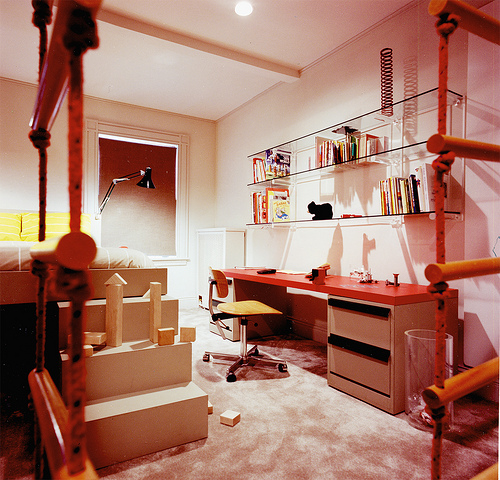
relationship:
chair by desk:
[217, 285, 261, 366] [293, 282, 294, 283]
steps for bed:
[128, 393, 187, 449] [6, 263, 32, 275]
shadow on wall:
[470, 422, 489, 439] [480, 287, 493, 311]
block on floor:
[110, 416, 155, 456] [342, 439, 356, 453]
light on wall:
[241, 0, 255, 23] [480, 287, 493, 311]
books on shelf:
[383, 172, 409, 206] [320, 201, 376, 223]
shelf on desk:
[320, 201, 376, 223] [293, 282, 294, 283]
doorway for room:
[114, 114, 191, 149] [57, 9, 485, 360]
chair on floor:
[217, 285, 261, 366] [342, 439, 356, 453]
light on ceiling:
[241, 0, 255, 23] [333, 6, 353, 13]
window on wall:
[177, 139, 193, 158] [480, 287, 493, 311]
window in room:
[177, 139, 193, 158] [57, 9, 485, 360]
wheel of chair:
[222, 371, 234, 383] [217, 285, 261, 366]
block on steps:
[110, 416, 155, 456] [128, 393, 187, 449]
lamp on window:
[99, 171, 158, 202] [177, 139, 193, 158]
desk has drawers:
[293, 282, 294, 283] [333, 274, 380, 353]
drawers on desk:
[333, 274, 380, 353] [293, 282, 294, 283]